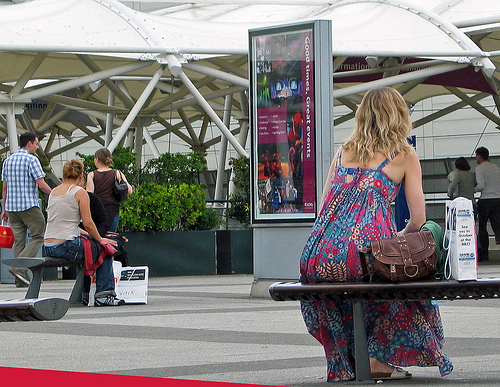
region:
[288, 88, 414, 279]
a woman sitting on a bench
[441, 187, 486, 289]
a shopping bag next to a woman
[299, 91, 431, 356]
a woman wearing a floral dress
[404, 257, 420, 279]
a metal buckle on a leather purse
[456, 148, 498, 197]
a man grasping a woman's arm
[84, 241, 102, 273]
a red strap hanging off a lap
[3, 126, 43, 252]
a man wearing a blue checkered shirt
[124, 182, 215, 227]
a shrub growing in a planter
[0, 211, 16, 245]
a hand holding a reds shopping bag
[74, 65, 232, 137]
metal supports under a roof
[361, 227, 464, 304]
a brown purse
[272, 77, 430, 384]
a woman wearing a dress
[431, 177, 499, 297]
a white shopping bag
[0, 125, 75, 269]
a man wearing a plaid shirt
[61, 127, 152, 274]
a woman carrying a purse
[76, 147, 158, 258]
a woman wearing a brown tank top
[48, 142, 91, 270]
a woman wearing a white tank top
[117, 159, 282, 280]
black flower boxes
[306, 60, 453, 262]
a woman with blonde hair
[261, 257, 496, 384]
a metal bench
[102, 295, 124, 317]
This woman is wearing black and blue shoes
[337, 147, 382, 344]
This woman is wearing a blue and red and peach dress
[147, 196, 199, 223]
These bushes are a bright, deep green color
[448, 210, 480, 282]
This woman purchased something that's in the white bag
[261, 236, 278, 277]
The color of this wall is a deep grey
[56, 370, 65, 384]
There is a thick red line on the cement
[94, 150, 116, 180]
This woman has her brown hair in a ponytail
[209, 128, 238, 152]
There is a white pipe that supports the structure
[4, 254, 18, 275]
This bench is a dark grey color and looks comfy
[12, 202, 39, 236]
This man is wearing green khaki pants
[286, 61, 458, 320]
A lady on the bench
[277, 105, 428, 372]
Women in a dress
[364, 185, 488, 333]
A pocketbook on the bench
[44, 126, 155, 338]
A bench for people to sit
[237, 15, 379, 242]
A sign on the walkway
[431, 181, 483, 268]
A shopping bag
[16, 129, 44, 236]
A man with a plaid shirt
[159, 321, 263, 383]
The walkway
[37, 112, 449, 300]
People walking around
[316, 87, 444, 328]
A woman resting from a long day of walking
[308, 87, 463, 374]
The woman is sitting down.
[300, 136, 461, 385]
The woman is wearing a long dress.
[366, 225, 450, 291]
The woman's purse is on the bench.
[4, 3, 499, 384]
The picture was taken inside a mall.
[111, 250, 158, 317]
The bag is sitting on the floor.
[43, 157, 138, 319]
The girl is sitting on a bench.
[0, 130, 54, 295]
The man is walking.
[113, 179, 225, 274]
There are plants growing in boxes.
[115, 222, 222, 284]
The planter boxes are green.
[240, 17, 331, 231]
The sign is encased.